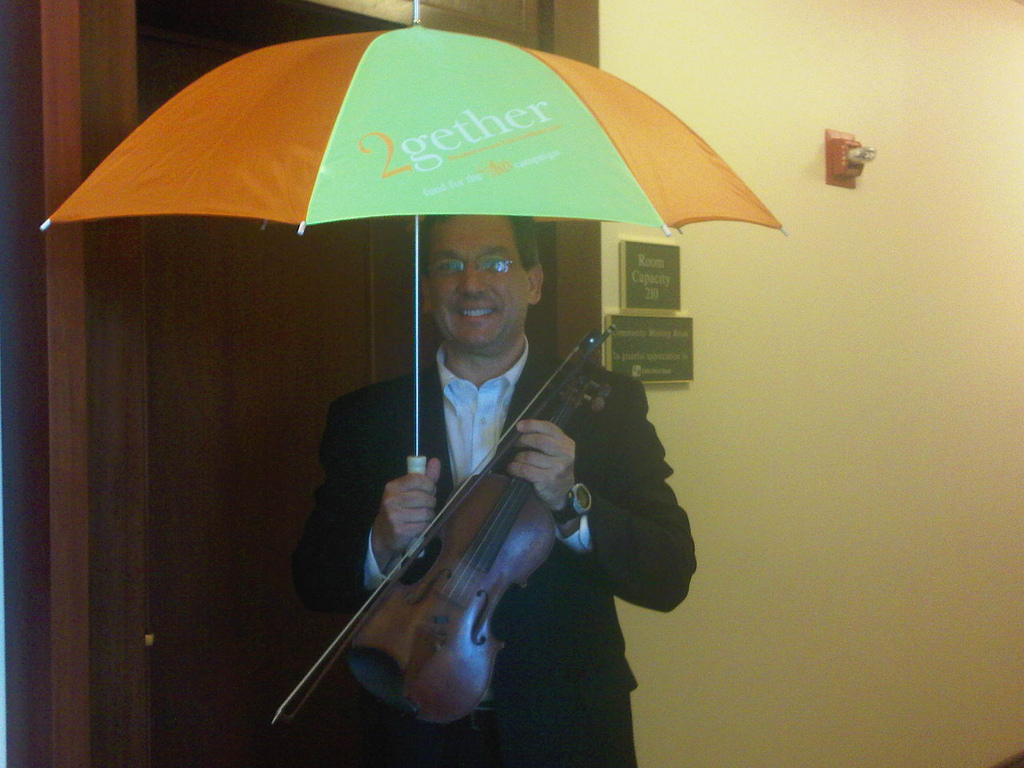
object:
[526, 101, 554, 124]
letter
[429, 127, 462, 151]
letter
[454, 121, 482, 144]
letter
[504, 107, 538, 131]
letter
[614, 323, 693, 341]
lettering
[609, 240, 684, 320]
frame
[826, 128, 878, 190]
alarm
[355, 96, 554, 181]
text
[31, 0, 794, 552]
umbrella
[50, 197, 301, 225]
color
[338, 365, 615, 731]
violin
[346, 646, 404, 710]
color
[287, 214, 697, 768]
man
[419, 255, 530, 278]
glasses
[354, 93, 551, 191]
logo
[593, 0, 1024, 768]
wall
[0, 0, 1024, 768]
building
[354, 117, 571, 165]
letters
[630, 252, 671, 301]
lettering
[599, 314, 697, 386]
frame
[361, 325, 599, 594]
shirt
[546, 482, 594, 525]
watch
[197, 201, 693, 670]
man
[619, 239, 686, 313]
plaque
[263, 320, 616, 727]
bow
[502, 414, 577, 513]
hand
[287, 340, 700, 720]
blazer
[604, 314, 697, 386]
placard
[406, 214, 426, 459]
pole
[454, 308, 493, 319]
teeth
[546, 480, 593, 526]
clock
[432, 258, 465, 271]
eye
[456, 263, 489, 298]
nose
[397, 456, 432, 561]
handle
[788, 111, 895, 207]
light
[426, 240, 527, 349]
face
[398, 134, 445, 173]
writings